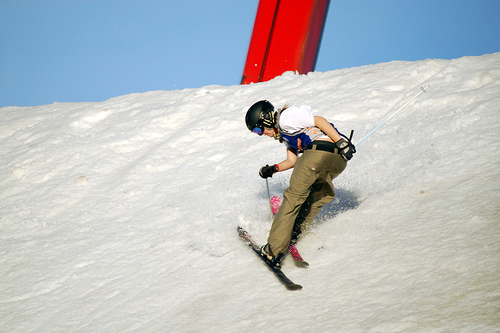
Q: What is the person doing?
A: They are skiing down a slope.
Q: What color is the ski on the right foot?
A: Pink.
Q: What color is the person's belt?
A: Black.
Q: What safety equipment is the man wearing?
A: A helmet.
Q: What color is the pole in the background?
A: Red.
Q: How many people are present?
A: One.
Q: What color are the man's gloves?
A: Black.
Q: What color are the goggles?
A: Blue.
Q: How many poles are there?
A: One.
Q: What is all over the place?
A: The snow.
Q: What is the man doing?
A: Skiing.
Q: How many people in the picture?
A: 1.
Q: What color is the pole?
A: Red.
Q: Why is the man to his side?
A: To slow down.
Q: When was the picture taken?
A: Daytime.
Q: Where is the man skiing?
A: The snow.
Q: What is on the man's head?
A: A helmet.